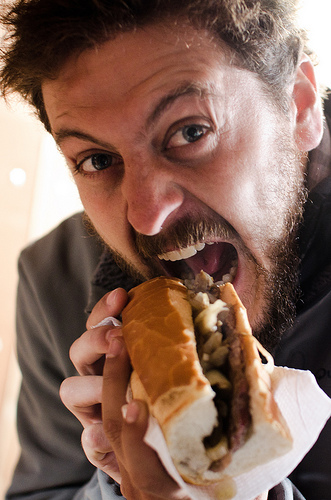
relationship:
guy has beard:
[0, 0, 330, 498] [260, 195, 303, 346]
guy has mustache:
[0, 0, 330, 498] [137, 232, 200, 244]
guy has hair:
[0, 0, 330, 498] [0, 3, 323, 122]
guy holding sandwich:
[0, 0, 330, 498] [117, 269, 296, 484]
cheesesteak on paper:
[121, 269, 293, 485] [261, 368, 329, 460]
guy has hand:
[0, 0, 330, 498] [68, 307, 155, 473]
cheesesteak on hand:
[121, 269, 293, 485] [68, 307, 155, 473]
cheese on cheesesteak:
[195, 299, 222, 332] [121, 271, 293, 486]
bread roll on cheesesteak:
[121, 276, 217, 484] [121, 269, 293, 485]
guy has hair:
[0, 0, 330, 498] [1, 0, 330, 134]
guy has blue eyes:
[0, 0, 330, 498] [164, 114, 214, 150]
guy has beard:
[0, 0, 330, 498] [72, 172, 317, 360]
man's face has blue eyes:
[10, 4, 323, 315] [63, 114, 229, 174]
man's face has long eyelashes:
[10, 4, 323, 315] [68, 153, 102, 176]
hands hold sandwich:
[57, 291, 166, 492] [124, 282, 265, 475]